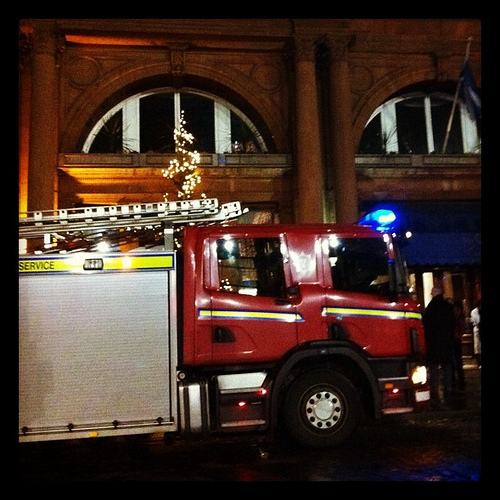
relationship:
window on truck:
[218, 232, 290, 301] [16, 200, 435, 447]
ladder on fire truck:
[37, 200, 252, 252] [26, 197, 437, 430]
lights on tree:
[184, 175, 198, 190] [155, 109, 210, 204]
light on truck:
[346, 200, 409, 230] [26, 219, 431, 416]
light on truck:
[92, 236, 116, 255] [16, 200, 435, 447]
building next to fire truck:
[20, 26, 493, 228] [1, 177, 441, 465]